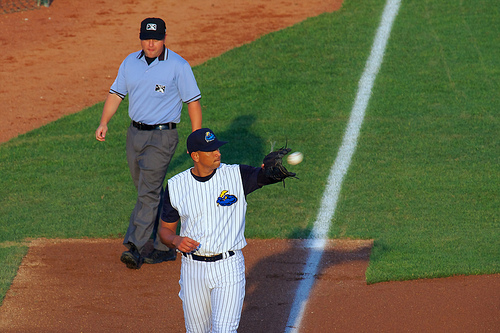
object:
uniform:
[160, 161, 263, 332]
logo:
[215, 189, 239, 208]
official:
[94, 17, 202, 269]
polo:
[110, 44, 203, 125]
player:
[157, 127, 296, 332]